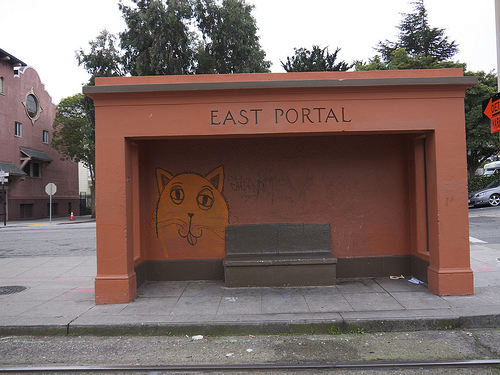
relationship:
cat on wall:
[153, 156, 232, 282] [141, 142, 417, 258]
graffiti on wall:
[225, 172, 335, 205] [141, 142, 417, 258]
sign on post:
[475, 88, 499, 135] [486, 5, 500, 51]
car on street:
[465, 184, 500, 208] [467, 207, 499, 251]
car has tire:
[465, 184, 500, 208] [487, 192, 499, 206]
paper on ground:
[383, 271, 424, 288] [147, 275, 430, 316]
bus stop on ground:
[88, 69, 486, 304] [147, 275, 430, 316]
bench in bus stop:
[222, 220, 339, 286] [88, 69, 486, 304]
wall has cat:
[141, 142, 417, 258] [153, 156, 232, 282]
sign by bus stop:
[475, 88, 499, 135] [88, 69, 486, 304]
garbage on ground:
[191, 332, 205, 343] [147, 275, 430, 316]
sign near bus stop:
[475, 88, 499, 135] [88, 69, 486, 304]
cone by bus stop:
[67, 207, 78, 224] [88, 69, 486, 304]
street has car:
[467, 207, 499, 251] [465, 184, 500, 208]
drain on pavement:
[1, 281, 28, 305] [3, 256, 100, 317]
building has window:
[0, 49, 79, 225] [22, 85, 44, 123]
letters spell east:
[206, 102, 372, 126] [205, 105, 270, 130]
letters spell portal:
[206, 102, 372, 126] [267, 105, 355, 124]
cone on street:
[67, 207, 78, 224] [467, 207, 499, 251]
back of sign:
[43, 181, 57, 197] [42, 179, 60, 223]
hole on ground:
[465, 330, 497, 361] [147, 275, 430, 316]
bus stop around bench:
[88, 69, 486, 304] [222, 220, 339, 286]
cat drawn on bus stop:
[153, 156, 232, 282] [88, 69, 486, 304]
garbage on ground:
[174, 332, 222, 346] [147, 275, 430, 316]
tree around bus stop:
[72, 1, 276, 64] [88, 69, 486, 304]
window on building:
[22, 85, 44, 123] [0, 49, 79, 225]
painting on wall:
[153, 156, 232, 282] [141, 142, 417, 258]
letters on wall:
[206, 102, 372, 126] [122, 77, 425, 128]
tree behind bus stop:
[72, 1, 276, 64] [88, 69, 486, 304]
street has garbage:
[467, 207, 499, 251] [191, 332, 205, 343]